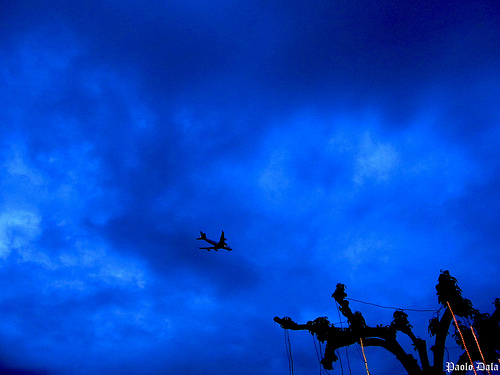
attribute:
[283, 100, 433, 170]
sky —  dark and cloudy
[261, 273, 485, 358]
tree — large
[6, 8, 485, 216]
sky — dark, blue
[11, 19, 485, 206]
sky — royal blue, colored, blue colored, royal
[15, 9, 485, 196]
sky — royal blue, colored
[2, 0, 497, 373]
sky — royal blue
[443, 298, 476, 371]
string — red